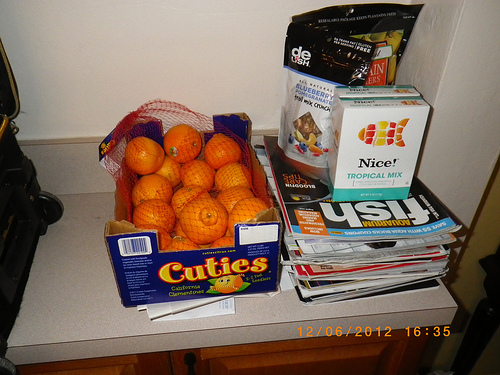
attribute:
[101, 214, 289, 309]
box — brown, blue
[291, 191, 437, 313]
magazines — stack, stacked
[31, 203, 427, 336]
counter — gray